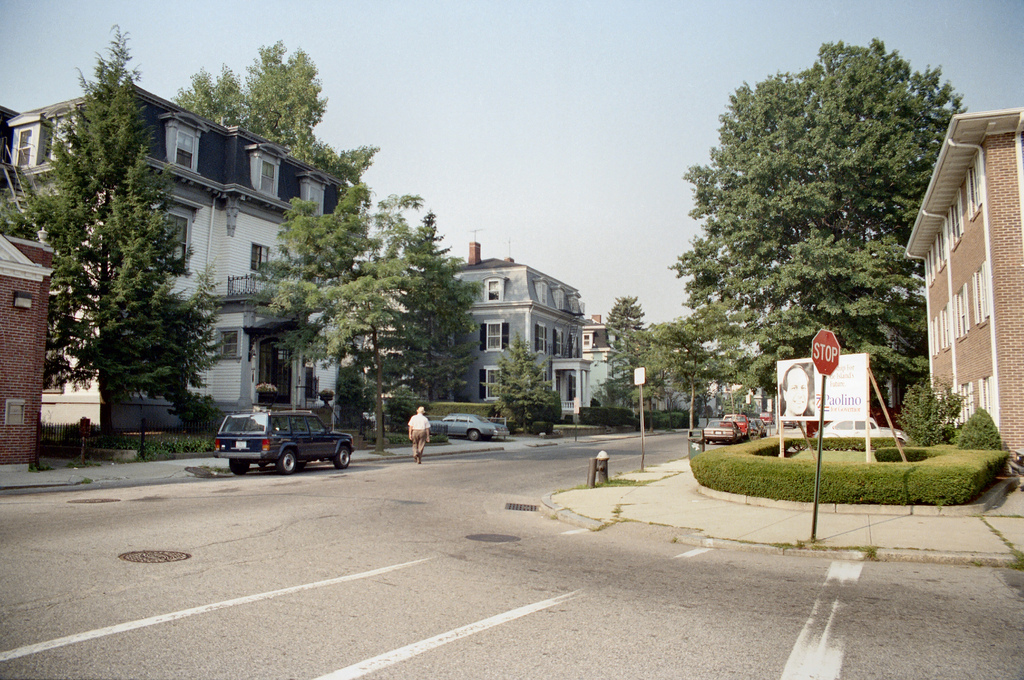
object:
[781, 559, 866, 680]
lines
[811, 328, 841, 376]
stop sign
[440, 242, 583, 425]
house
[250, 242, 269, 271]
window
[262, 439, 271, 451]
lights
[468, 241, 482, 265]
chimney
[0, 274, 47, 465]
wall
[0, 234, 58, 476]
building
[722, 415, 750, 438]
cars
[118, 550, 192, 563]
cover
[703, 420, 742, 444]
cars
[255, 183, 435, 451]
tree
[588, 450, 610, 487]
fire hydrant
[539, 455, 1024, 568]
street curb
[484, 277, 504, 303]
window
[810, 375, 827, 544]
pole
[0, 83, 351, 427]
house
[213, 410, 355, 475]
jeep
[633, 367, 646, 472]
street sign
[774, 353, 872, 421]
billboard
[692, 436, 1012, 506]
lawn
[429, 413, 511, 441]
car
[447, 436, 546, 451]
driveway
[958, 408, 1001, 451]
bush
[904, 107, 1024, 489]
building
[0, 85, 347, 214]
upper level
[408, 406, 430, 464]
man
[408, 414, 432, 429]
shirt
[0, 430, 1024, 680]
road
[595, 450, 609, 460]
top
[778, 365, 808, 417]
man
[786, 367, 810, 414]
face